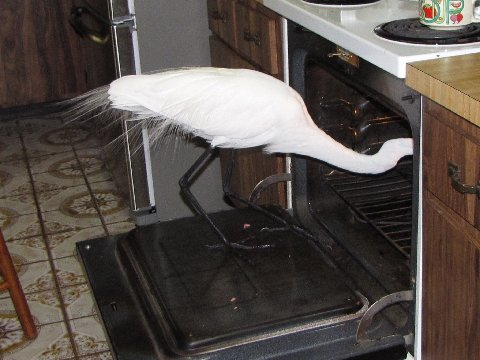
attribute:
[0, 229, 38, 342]
leg — wooden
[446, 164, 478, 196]
metal — black 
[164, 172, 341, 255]
feet — black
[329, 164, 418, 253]
rack — metal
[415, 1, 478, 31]
mug — white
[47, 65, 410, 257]
crane — white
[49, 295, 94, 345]
floor — beige, gold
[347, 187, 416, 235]
rack — metal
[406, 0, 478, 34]
mug — coffee mug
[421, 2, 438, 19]
logo — red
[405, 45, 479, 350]
counter — old, cheep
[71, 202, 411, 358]
door — open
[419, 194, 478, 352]
cabinet — wooden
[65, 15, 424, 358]
oven — white, gray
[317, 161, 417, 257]
rack — black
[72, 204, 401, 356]
oven door — open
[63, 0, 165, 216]
door — refrigerator door, gray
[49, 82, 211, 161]
feathers — soft, white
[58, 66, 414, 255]
bird — white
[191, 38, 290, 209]
cabinet — dark wooden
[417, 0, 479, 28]
dish — ceramic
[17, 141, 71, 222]
floor — tiled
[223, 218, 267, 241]
foot — black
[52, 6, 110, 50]
handle — metallic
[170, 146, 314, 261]
legs — bend